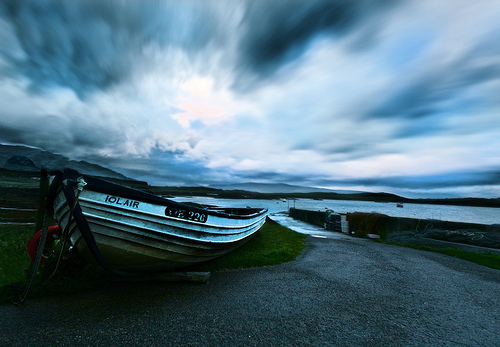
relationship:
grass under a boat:
[174, 212, 313, 268] [14, 164, 269, 316]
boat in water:
[0, 140, 500, 284] [160, 191, 497, 241]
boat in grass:
[0, 140, 500, 284] [2, 171, 310, 278]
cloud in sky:
[224, 0, 369, 92] [0, 0, 498, 147]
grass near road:
[174, 212, 318, 268] [5, 204, 498, 345]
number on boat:
[165, 204, 209, 223] [87, 167, 287, 267]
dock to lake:
[251, 206, 398, 217] [234, 174, 486, 226]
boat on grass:
[71, 171, 277, 283] [242, 225, 307, 270]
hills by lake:
[0, 141, 500, 280] [158, 189, 498, 225]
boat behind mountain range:
[0, 140, 500, 284] [1, 139, 146, 185]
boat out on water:
[0, 140, 500, 284] [269, 186, 499, 233]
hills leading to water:
[1, 141, 138, 191] [161, 186, 496, 251]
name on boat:
[100, 192, 141, 211] [47, 162, 269, 287]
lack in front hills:
[262, 183, 357, 228] [191, 134, 441, 269]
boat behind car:
[0, 140, 500, 284] [7, 162, 153, 270]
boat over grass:
[0, 140, 500, 284] [230, 222, 303, 267]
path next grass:
[97, 209, 494, 344] [256, 216, 308, 265]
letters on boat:
[103, 191, 139, 210] [75, 167, 303, 265]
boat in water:
[0, 140, 500, 284] [180, 191, 493, 225]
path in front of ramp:
[0, 209, 500, 347] [271, 213, 350, 236]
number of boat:
[167, 204, 211, 229] [49, 166, 271, 268]